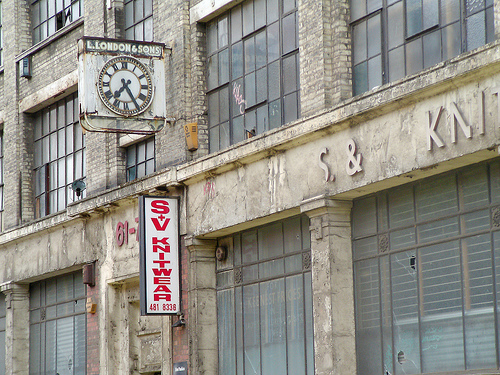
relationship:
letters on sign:
[158, 239, 166, 264] [142, 199, 182, 315]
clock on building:
[76, 36, 165, 135] [4, 3, 499, 371]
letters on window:
[231, 80, 246, 118] [226, 77, 243, 141]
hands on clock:
[113, 77, 141, 107] [75, 35, 172, 139]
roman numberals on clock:
[121, 60, 128, 72] [90, 54, 157, 114]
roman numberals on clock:
[131, 60, 137, 73] [90, 54, 157, 114]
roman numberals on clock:
[136, 71, 147, 81] [90, 54, 157, 114]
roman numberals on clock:
[137, 80, 149, 90] [90, 54, 157, 114]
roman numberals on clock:
[136, 90, 147, 102] [90, 54, 157, 114]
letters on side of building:
[308, 85, 498, 195] [4, 3, 499, 371]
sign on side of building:
[138, 196, 182, 317] [4, 3, 499, 371]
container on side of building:
[183, 120, 199, 150] [4, 3, 499, 371]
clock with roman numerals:
[76, 36, 165, 135] [132, 67, 149, 91]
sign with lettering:
[135, 192, 194, 319] [149, 203, 172, 303]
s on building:
[315, 141, 337, 189] [4, 3, 499, 371]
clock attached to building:
[67, 32, 169, 139] [4, 3, 499, 371]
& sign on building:
[341, 137, 366, 193] [4, 3, 499, 371]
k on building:
[426, 102, 443, 149] [4, 3, 499, 371]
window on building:
[355, 195, 381, 367] [4, 3, 499, 371]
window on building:
[388, 178, 415, 365] [4, 3, 499, 371]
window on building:
[422, 172, 458, 367] [4, 3, 499, 371]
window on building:
[458, 169, 498, 361] [4, 3, 499, 371]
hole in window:
[406, 255, 418, 275] [382, 249, 419, 351]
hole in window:
[395, 349, 407, 366] [382, 249, 419, 351]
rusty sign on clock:
[77, 35, 165, 58] [79, 51, 167, 118]